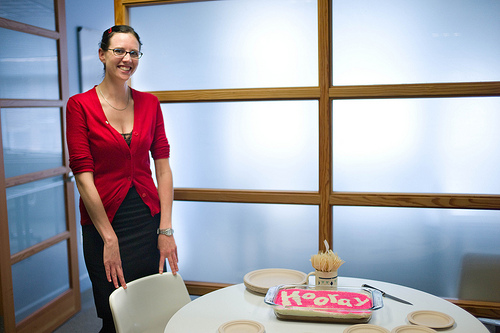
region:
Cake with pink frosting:
[258, 270, 392, 318]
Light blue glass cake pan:
[255, 271, 390, 326]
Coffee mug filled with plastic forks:
[302, 245, 352, 297]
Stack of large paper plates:
[233, 253, 315, 302]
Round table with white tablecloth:
[133, 255, 491, 332]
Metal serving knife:
[358, 275, 429, 325]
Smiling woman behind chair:
[55, 10, 215, 331]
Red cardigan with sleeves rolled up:
[31, 82, 203, 252]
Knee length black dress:
[69, 98, 177, 323]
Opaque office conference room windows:
[73, 55, 490, 222]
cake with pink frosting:
[267, 280, 382, 317]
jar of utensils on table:
[310, 250, 349, 287]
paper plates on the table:
[241, 265, 305, 291]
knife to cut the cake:
[361, 278, 416, 309]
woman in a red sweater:
[56, 17, 192, 328]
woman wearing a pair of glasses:
[83, 21, 155, 91]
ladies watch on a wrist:
[148, 220, 183, 244]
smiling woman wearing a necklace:
[42, 12, 207, 135]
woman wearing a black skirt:
[75, 172, 199, 328]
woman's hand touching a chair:
[92, 227, 186, 290]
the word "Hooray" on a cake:
[280, 290, 374, 312]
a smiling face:
[111, 36, 141, 79]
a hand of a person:
[100, 234, 131, 291]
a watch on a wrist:
[154, 225, 179, 239]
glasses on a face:
[110, 42, 144, 62]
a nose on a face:
[119, 51, 135, 63]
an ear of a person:
[94, 45, 110, 67]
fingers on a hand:
[101, 256, 130, 295]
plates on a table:
[241, 269, 259, 299]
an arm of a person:
[151, 126, 177, 217]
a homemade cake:
[266, 287, 370, 319]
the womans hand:
[96, 239, 132, 296]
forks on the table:
[305, 239, 342, 282]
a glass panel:
[219, 115, 284, 135]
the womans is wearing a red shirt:
[107, 149, 124, 183]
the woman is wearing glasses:
[103, 17, 174, 92]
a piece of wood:
[254, 89, 285, 96]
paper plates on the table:
[253, 259, 308, 285]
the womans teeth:
[118, 62, 131, 72]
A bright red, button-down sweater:
[61, 84, 172, 228]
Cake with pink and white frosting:
[266, 284, 386, 322]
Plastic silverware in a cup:
[309, 242, 346, 291]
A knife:
[362, 281, 415, 309]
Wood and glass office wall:
[108, 0, 495, 310]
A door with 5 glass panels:
[1, 3, 81, 328]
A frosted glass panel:
[328, 94, 497, 197]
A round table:
[159, 269, 492, 330]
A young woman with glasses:
[97, 26, 144, 85]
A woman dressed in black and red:
[71, 22, 174, 329]